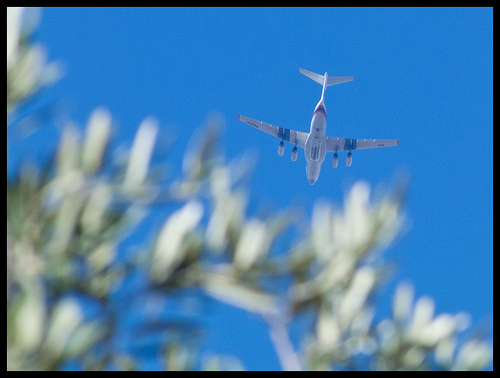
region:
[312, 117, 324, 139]
the plain is white and red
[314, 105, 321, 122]
the plain is white and red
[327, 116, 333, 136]
the plain is white and red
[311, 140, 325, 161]
the plain is white and red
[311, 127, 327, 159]
the plain is white and red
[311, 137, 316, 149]
the plain is white and red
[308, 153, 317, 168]
the plain is white and red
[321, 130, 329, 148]
the plain is white and red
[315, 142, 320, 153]
the plain is white and red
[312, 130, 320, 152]
the plain is white and red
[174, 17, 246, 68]
this is the sky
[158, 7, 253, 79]
the sky is blue in color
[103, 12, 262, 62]
the sky is clear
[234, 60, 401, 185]
this is an airplane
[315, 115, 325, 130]
the airplane is white in color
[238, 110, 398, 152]
these are the wings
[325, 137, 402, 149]
the wing is long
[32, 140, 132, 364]
this is a tree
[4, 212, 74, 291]
the leaves are green in color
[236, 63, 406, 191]
the airplane is in the air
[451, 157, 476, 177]
section of blue sky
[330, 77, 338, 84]
back wing of a plane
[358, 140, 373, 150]
left wing of a plane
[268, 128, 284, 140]
right wing on a plane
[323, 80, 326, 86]
back part of a plane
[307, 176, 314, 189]
front part of a plane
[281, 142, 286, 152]
fan of a plane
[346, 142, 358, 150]
blue part of a plane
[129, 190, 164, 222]
branches of a tree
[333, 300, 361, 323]
leaves of a tree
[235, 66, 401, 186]
white and blue airplane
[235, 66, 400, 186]
airplane preparing to land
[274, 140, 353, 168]
four engines on the plane's wings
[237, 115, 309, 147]
left wing on the blue and white airplane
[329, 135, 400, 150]
white and blue right wing on the airplane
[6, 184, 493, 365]
blurry picture of leaves on branches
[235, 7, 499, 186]
airplane flying in the blue sky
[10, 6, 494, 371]
airplane flying over tree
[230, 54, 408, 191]
jet flying over a tree in the sky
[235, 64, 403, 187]
jet preparing to land on the airport's runway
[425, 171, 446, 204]
the sky is clear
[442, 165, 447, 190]
the sky is clear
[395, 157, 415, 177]
the sky is clear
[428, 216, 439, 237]
the sky is clear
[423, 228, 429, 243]
the sky is clear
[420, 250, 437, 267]
the sky is clear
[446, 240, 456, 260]
the sky is clear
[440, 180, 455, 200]
the sky is clear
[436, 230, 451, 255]
the sky is clear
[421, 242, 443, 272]
the sky is clear